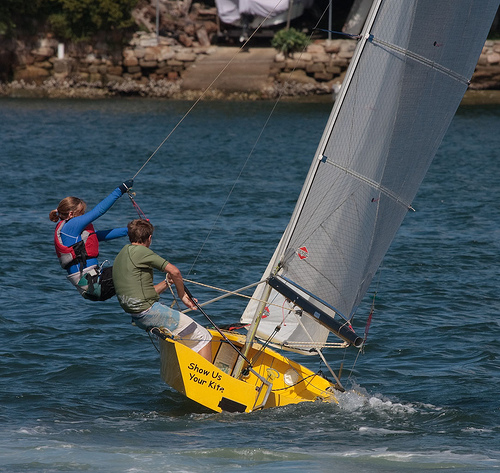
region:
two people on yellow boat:
[27, 122, 347, 457]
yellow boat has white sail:
[188, 0, 433, 418]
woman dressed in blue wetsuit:
[38, 178, 122, 306]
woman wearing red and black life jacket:
[32, 195, 104, 262]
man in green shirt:
[102, 182, 163, 320]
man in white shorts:
[130, 281, 228, 352]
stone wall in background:
[34, 31, 462, 168]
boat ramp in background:
[191, 12, 305, 133]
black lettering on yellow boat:
[148, 347, 256, 411]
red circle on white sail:
[278, 224, 326, 279]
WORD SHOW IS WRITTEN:
[190, 356, 207, 383]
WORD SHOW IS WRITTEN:
[184, 363, 208, 391]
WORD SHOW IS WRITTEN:
[177, 345, 203, 388]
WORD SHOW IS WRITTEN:
[196, 365, 207, 379]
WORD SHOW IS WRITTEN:
[187, 357, 202, 374]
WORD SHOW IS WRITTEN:
[189, 365, 204, 375]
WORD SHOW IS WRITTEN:
[196, 365, 208, 372]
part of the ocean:
[405, 388, 422, 414]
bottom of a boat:
[202, 395, 224, 421]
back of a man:
[128, 242, 134, 291]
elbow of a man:
[170, 258, 177, 287]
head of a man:
[135, 225, 152, 234]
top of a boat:
[303, 261, 313, 281]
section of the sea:
[441, 312, 453, 319]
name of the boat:
[194, 367, 198, 378]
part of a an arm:
[88, 222, 104, 224]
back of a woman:
[71, 242, 80, 257]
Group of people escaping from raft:
[44, 178, 224, 356]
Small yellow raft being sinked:
[147, 2, 495, 417]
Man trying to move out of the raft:
[111, 212, 221, 357]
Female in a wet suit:
[48, 177, 148, 305]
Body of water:
[1, 95, 498, 470]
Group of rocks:
[2, 2, 497, 99]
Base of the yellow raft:
[155, 327, 339, 419]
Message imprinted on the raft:
[185, 361, 226, 396]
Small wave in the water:
[8, 388, 488, 469]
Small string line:
[130, 4, 288, 182]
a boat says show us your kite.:
[160, 350, 250, 415]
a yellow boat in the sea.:
[145, 320, 350, 425]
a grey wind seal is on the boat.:
[265, 0, 495, 335]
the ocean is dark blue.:
[395, 265, 495, 370]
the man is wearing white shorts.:
[125, 300, 205, 345]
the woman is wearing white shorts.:
[65, 260, 105, 300]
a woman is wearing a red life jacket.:
[45, 215, 95, 255]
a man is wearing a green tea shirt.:
[100, 245, 165, 310]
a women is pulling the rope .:
[31, 150, 132, 250]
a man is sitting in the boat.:
[107, 200, 212, 366]